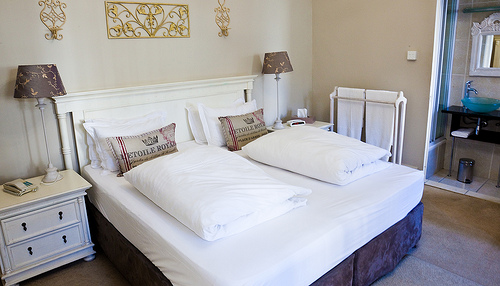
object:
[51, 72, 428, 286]
bed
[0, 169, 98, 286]
nightstand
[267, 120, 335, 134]
nightstand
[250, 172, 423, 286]
bedskirt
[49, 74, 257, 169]
headboard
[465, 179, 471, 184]
foot pedal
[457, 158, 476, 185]
trashcan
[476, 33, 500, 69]
mirror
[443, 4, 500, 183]
wall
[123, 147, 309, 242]
bedding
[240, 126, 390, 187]
bedding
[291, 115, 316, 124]
box of tissues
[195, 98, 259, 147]
pillows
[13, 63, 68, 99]
lamp cover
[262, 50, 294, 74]
lamp cover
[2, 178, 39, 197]
telephone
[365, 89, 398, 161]
towels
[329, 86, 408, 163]
rack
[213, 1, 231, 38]
decorations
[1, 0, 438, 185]
wall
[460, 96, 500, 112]
sink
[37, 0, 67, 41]
decoration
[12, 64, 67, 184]
lamp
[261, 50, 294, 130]
lamp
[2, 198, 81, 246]
drawers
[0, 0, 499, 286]
bathroom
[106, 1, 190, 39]
decoration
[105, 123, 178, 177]
decorative pillow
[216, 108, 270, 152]
decorative pillow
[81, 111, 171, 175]
pillows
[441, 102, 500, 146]
shelf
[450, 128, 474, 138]
towel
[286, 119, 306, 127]
alarm clock